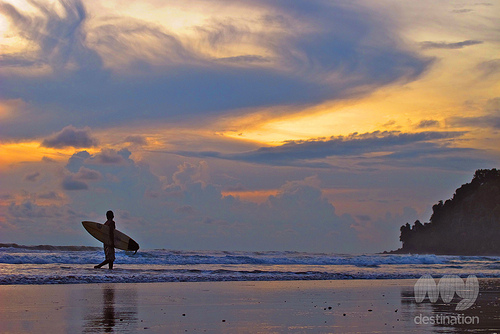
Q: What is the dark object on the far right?
A: Rocky cliff.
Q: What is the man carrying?
A: A surfboard.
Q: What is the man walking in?
A: Water.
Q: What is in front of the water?
A: The beach.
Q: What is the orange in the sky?
A: Sunlight.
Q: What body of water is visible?
A: The ocean.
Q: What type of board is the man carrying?
A: A surfboard.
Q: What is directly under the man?
A: A shadow.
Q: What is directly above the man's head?
A: Clouds.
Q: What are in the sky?
A: Gray, orange clouds.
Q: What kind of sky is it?
A: Grey and orange sky.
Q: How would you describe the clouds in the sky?
A: Gray and orange.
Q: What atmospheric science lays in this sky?
A: Clouds.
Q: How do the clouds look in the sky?
A: Fluffy.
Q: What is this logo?
A: The logo of the photographer.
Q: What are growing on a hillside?
A: Trees.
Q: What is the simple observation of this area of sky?
A: There is a white cloud.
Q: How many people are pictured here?
A: One.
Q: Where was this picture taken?
A: The ocean.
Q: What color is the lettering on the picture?
A: White.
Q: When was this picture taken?
A: Sunset.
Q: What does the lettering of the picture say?
A: My destination.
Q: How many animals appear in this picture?
A: Zero.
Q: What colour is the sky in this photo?
A: Orange and white.